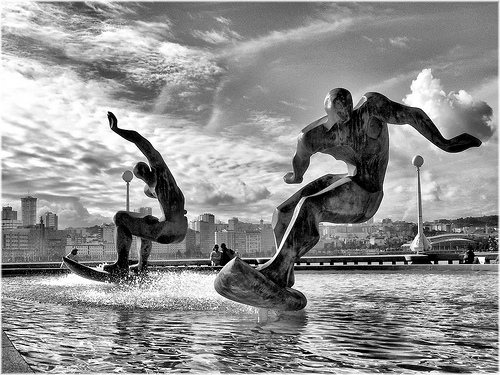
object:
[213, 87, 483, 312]
sculpture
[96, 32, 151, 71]
clouds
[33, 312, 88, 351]
water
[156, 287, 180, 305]
droplets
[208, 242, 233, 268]
couple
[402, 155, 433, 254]
structure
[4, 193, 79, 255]
building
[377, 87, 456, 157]
arm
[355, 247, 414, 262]
water bridge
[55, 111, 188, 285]
statue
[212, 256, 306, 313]
surfboard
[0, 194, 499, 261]
city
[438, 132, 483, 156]
hand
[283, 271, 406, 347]
pool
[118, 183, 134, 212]
poles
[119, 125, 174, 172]
arms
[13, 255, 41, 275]
railing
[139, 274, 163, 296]
spray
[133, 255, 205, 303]
waves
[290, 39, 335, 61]
sky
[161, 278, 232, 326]
reflection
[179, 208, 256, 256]
buildings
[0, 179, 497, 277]
background